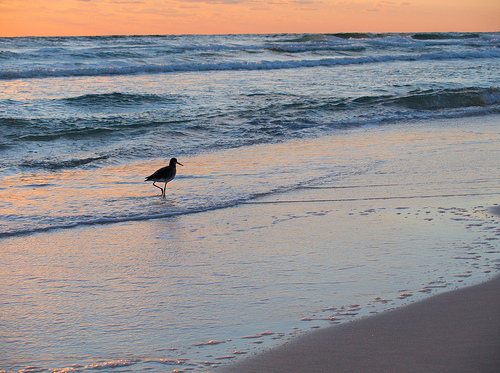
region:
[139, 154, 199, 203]
bird walking in water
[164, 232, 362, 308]
water standing on beach sand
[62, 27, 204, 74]
waves forming on water surface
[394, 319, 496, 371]
wet sand on beach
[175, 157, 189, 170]
long bill on bird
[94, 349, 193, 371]
white sea foam on water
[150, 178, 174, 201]
long yellow bird legs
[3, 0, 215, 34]
evening sky above water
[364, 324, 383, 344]
small rock laying on beach sand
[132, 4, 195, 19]
small white cloud in evening sky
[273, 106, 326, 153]
edge of a wave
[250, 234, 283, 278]
part of a water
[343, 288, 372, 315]
par tof a water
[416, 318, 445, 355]
part of a shore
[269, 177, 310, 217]
edge of a water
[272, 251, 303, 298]
part of a liner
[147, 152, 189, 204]
this is a bird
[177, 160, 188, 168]
this is a beak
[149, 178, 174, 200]
these are the legs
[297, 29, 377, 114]
these are the waves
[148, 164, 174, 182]
these are the feathers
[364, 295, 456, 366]
this is the beach sand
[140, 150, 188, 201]
the bird is walking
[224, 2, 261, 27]
this is the sky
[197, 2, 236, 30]
the sky is cream in color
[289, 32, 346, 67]
the waves are heavy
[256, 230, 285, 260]
part of the sea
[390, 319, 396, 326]
part of a ocean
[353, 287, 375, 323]
edge of the ocean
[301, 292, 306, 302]
part of a wave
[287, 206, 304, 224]
edge of the sea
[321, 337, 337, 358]
part of a water body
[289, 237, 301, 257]
part of the ocean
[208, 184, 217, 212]
part of the water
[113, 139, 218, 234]
bird is in water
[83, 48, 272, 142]
the water is wavy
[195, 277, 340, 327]
the water at the front is calm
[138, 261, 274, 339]
water at the front is coorles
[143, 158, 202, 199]
the bird is black in color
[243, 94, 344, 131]
the wayter at the background is bvlue in color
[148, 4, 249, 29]
the sky is cloudy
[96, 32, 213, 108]
suns ray are reflected 9on watrer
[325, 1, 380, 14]
sky is clear in color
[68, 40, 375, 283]
picture was taken at sunset